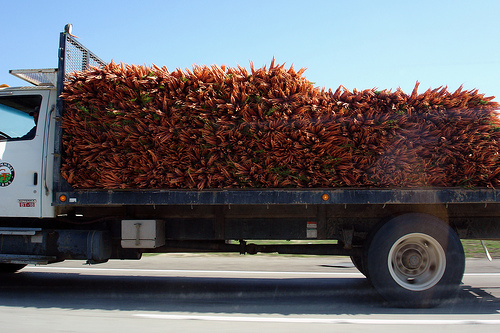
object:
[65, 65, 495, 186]
plants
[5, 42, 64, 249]
truck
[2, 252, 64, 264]
step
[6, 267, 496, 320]
shadow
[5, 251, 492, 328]
ground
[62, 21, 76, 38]
bird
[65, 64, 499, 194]
pile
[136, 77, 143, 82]
plant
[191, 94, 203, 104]
plant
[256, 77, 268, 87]
plant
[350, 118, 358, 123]
plant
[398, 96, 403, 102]
plant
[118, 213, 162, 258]
box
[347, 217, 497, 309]
tire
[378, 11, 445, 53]
sky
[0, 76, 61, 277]
front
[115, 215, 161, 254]
white box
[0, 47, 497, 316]
truck trailer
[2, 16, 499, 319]
truck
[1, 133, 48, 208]
cab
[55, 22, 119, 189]
back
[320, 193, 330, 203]
light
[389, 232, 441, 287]
rim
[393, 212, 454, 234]
truck tire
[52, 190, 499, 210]
flatbed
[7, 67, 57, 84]
wire ledge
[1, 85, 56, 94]
truck roof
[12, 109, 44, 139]
driver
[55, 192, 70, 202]
light